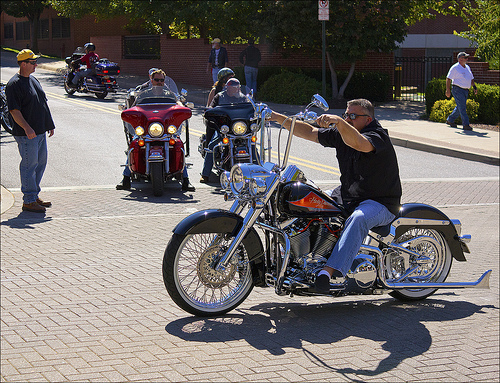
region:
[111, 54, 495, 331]
People riding on motorcycles.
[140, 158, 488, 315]
A black motorcycle on street.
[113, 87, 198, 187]
A red motorcycle on street.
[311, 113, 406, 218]
Man dressed in black shirt.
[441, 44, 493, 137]
Man walking down sidewalk.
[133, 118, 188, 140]
Headlights on front of motorcycle.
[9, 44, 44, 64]
Man wearing yellow cap.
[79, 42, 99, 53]
Man wearing helmet on head.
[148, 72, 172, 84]
Man wearing sunglasses over eyes.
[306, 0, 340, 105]
Traffic sign on sidewalk.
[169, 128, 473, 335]
this is a motorbike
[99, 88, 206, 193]
this is a motorbike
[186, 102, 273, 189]
this is a motorbike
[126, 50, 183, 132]
this is a person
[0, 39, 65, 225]
this is a person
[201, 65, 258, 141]
this is a person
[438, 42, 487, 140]
this is a person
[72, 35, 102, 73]
this is a person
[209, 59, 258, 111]
this is a person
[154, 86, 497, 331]
Man on the motorcycle.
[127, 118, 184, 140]
Headlights on the motorcycle.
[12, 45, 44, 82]
Yellow hat on the man.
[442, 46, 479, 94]
Man in white shirt.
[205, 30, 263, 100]
People walking on the sidewalk.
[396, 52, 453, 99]
Black wrought iron gate.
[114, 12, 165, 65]
Window in the building.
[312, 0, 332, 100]
Sign on the side of the street.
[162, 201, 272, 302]
Black fender on the tire.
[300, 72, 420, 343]
this is a man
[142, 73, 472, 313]
a man riding a motorcycle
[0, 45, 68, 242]
man standing ont road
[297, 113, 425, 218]
man wearing a black shirt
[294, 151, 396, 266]
man wearing blue jeans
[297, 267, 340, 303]
man wearing black shoes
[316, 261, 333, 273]
man wearing white shoes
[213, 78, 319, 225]
'chrome handles on bike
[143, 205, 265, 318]
chrome rims on tires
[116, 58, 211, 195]
people riding a red motorcycle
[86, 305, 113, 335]
part of a floor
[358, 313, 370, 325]
part of a shade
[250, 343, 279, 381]
part of a floor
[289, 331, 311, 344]
edge of a shade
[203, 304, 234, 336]
part of a whelll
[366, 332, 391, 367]
part of a shade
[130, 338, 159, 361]
part of a floor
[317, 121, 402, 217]
Black shirt on a man.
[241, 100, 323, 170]
Silver handle bars on a motorcycle.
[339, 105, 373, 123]
Sunglasses on a man.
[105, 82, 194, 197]
Red motorcycle on a road.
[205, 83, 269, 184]
Black motorcycle on a road.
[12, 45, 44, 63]
Yellow hat on a man.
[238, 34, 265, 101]
Person walking on a sidewalk.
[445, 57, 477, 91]
White shirt on a man.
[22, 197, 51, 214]
Brown shoes on a man.